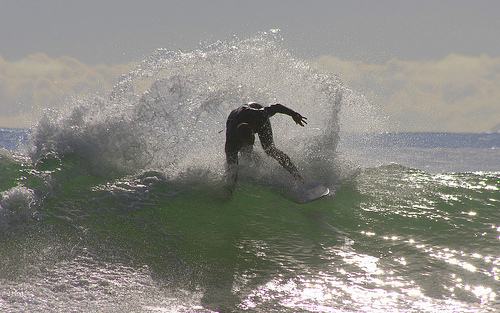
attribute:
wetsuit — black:
[223, 102, 305, 183]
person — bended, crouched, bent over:
[225, 99, 309, 192]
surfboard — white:
[264, 170, 330, 205]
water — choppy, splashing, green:
[8, 160, 499, 312]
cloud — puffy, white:
[393, 54, 500, 134]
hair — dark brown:
[235, 122, 250, 137]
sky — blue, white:
[0, 1, 499, 133]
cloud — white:
[0, 52, 64, 121]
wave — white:
[139, 142, 349, 203]